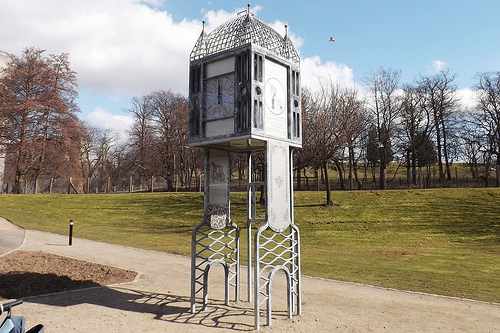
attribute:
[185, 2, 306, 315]
stand — silver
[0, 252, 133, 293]
dirt — brown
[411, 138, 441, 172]
ground — minute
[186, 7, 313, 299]
clock tower — small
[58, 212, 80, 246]
pole — short, black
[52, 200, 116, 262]
pole — black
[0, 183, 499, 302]
lawn — green, manicured, Trimmed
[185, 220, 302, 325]
metal base — grey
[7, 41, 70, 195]
tree — tall, reddish, brown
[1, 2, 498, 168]
sky — blue, white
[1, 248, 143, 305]
flower bed — umplanted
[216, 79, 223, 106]
hands — black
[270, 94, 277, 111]
hands — black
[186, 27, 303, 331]
tower — small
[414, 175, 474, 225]
grass — green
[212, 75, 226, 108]
handle — hour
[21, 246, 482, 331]
concrete — light tan